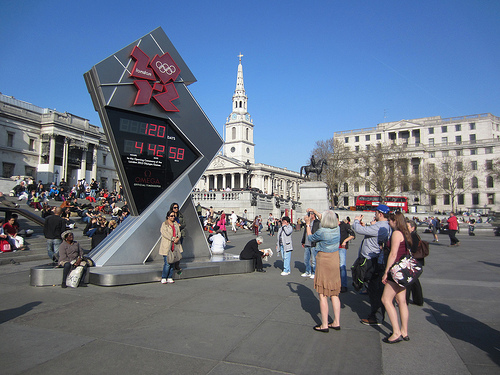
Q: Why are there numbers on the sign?
A: Countdown.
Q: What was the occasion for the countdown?
A: London 2012 Olympics.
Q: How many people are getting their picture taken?
A: Two.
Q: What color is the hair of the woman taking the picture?
A: Gray.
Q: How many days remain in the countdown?
A: 120.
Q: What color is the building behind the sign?
A: White.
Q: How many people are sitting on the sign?
A: Three.